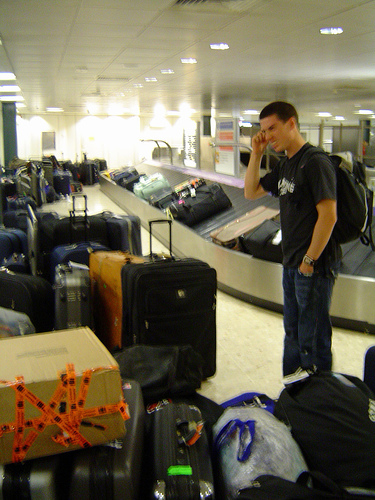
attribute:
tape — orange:
[45, 394, 73, 419]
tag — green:
[162, 462, 194, 475]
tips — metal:
[147, 481, 204, 498]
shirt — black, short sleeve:
[263, 163, 350, 267]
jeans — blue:
[280, 270, 327, 376]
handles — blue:
[211, 392, 283, 458]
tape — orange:
[2, 362, 128, 460]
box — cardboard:
[2, 324, 128, 463]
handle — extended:
[149, 216, 172, 254]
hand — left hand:
[299, 255, 313, 277]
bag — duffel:
[213, 388, 309, 497]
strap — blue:
[210, 391, 281, 461]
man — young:
[245, 101, 340, 373]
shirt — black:
[259, 143, 342, 278]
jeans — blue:
[281, 244, 338, 375]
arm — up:
[241, 132, 277, 199]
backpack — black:
[326, 156, 372, 250]